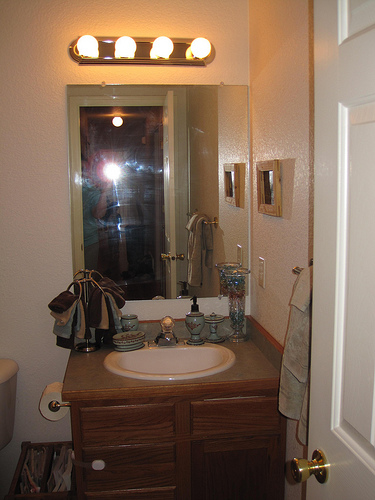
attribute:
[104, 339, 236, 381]
sink — white, silver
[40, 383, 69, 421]
toilet paper — white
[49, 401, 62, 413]
roll — white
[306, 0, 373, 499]
door — white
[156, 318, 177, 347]
faucet — silver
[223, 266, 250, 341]
vase — glass, tall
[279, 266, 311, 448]
towel — hanging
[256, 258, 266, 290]
outlet — white, small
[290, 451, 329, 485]
knob — gold, golden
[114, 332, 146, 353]
soap dish — empty, tall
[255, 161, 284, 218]
picture — wooden, small, brown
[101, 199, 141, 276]
shirt — green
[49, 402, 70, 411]
roll holder — golden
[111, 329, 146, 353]
soap dispensor — ceramic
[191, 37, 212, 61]
light — small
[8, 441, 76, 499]
book crate — wooden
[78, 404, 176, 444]
drawer — wooden`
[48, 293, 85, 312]
towel — brown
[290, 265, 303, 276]
towel hanger — silver